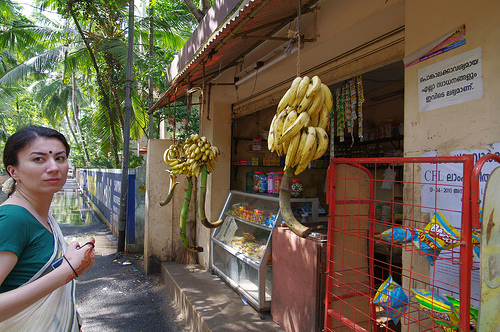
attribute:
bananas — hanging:
[264, 74, 337, 178]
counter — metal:
[182, 191, 322, 310]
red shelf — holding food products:
[321, 151, 498, 329]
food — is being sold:
[313, 199, 445, 301]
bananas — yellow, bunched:
[253, 87, 386, 222]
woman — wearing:
[6, 116, 100, 327]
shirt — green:
[8, 206, 100, 313]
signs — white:
[395, 37, 492, 209]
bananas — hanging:
[259, 73, 351, 177]